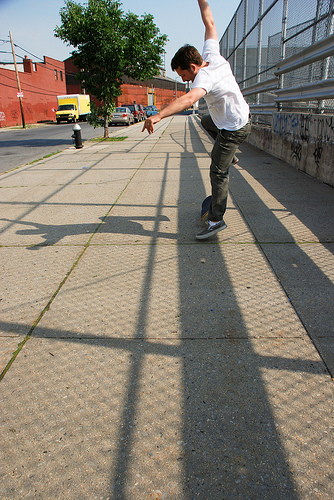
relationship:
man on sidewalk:
[142, 0, 259, 242] [87, 134, 329, 312]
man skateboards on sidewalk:
[142, 0, 259, 242] [1, 113, 331, 499]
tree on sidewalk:
[53, 1, 170, 139] [9, 102, 330, 477]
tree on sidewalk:
[53, 1, 170, 139] [7, 120, 167, 292]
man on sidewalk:
[142, 0, 259, 242] [1, 113, 331, 499]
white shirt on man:
[141, 0, 250, 241] [188, 38, 250, 131]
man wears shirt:
[142, 0, 259, 242] [186, 41, 248, 129]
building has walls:
[3, 44, 77, 127] [17, 55, 100, 139]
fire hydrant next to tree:
[69, 121, 85, 149] [53, 1, 164, 139]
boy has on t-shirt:
[169, 17, 281, 245] [152, 37, 257, 127]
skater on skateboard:
[125, 26, 263, 231] [193, 186, 212, 235]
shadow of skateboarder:
[5, 207, 186, 250] [143, 3, 250, 240]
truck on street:
[56, 73, 113, 127] [25, 117, 61, 153]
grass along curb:
[85, 130, 132, 148] [56, 135, 91, 155]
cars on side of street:
[84, 97, 140, 127] [4, 124, 110, 142]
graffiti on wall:
[275, 106, 327, 162] [268, 102, 325, 165]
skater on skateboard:
[140, 0, 252, 241] [192, 191, 212, 223]